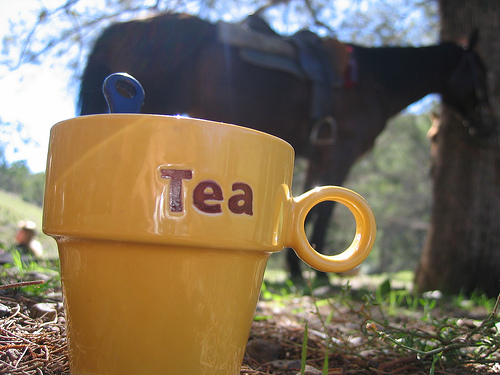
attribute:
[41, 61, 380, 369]
tea pot — brown, small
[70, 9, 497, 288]
horse — dark brown, standing, brown, wearing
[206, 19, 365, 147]
saddle — leather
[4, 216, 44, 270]
guy — sitting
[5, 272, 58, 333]
bundle — sticks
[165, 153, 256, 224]
letters — red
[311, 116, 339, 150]
stirrup — silver, attached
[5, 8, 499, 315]
tree — brown, tall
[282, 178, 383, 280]
tea handle — brown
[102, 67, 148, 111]
handle — blue, sticking out, round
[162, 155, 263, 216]
tea — written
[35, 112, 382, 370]
mug — yellow, sitting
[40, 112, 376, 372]
tea cup — gold, sitting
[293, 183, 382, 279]
handle — pointing, round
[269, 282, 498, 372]
weeds — growing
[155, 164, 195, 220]
letter — t, red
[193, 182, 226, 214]
letter — red, e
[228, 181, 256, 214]
letter — red, a